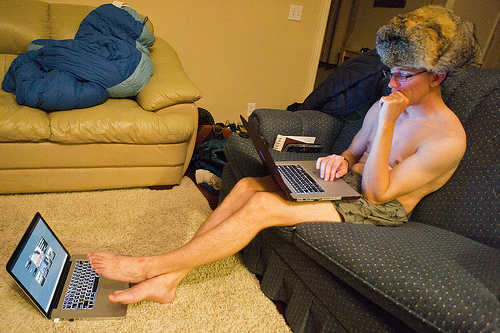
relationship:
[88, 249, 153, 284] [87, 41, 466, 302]
foot of person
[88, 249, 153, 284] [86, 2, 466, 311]
foot of person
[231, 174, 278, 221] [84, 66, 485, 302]
knee of person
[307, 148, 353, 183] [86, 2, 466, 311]
hand of person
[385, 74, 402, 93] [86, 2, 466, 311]
nose of person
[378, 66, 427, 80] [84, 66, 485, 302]
glasses of person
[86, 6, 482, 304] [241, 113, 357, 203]
man using laptop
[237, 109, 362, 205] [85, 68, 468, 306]
laptop used by man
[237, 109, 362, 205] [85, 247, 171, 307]
laptop at feet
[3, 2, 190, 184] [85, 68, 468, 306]
couch sat on by man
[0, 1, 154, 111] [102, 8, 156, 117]
blanket on sleeping bag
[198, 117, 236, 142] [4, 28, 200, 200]
backpack next couche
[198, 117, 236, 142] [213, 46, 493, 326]
backpack next couche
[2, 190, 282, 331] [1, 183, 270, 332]
rug on floor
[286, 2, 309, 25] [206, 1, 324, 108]
switches on wall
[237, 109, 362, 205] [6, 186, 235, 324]
laptop on floor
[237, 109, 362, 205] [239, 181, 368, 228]
laptop on lap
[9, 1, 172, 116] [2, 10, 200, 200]
blanket on couch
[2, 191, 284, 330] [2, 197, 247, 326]
carpet on floor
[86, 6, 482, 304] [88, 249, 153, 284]
man has foot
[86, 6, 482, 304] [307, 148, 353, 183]
man has hand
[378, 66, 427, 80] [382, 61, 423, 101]
glasses on face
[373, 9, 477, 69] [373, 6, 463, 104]
hat on head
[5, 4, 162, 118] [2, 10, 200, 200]
bag on couch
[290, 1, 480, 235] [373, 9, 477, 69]
man wears hat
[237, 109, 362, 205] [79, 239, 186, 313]
laptop has feet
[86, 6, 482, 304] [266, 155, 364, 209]
man has laptop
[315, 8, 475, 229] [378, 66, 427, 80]
man wears glasses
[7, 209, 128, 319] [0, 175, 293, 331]
laptop on floor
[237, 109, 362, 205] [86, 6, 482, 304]
laptop on lap of man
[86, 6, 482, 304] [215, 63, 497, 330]
man sitting on couch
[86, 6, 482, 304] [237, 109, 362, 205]
man looking at laptop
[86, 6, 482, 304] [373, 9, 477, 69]
man wearing hat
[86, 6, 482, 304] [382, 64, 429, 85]
man wearing glasses